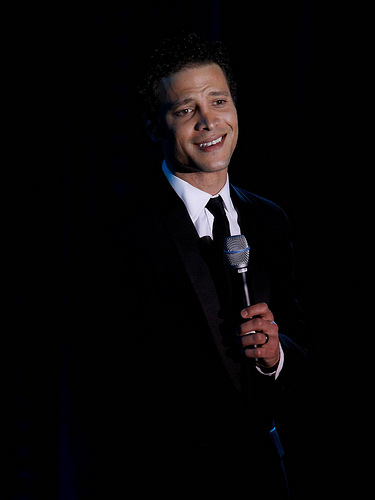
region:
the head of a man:
[131, 59, 275, 172]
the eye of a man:
[163, 93, 206, 133]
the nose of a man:
[191, 93, 227, 142]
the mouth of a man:
[187, 121, 251, 163]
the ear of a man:
[140, 110, 172, 159]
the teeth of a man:
[187, 121, 248, 169]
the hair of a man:
[147, 16, 257, 123]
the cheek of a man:
[166, 88, 218, 167]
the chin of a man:
[185, 160, 242, 206]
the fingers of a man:
[229, 299, 280, 398]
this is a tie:
[211, 198, 230, 231]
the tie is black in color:
[207, 199, 223, 231]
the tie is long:
[208, 197, 230, 225]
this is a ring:
[259, 334, 270, 346]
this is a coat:
[107, 227, 155, 319]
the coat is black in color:
[113, 305, 188, 428]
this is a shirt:
[192, 193, 207, 217]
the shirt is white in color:
[190, 191, 202, 203]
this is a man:
[143, 46, 320, 356]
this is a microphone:
[220, 237, 264, 307]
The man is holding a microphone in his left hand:
[224, 234, 276, 370]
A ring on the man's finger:
[261, 333, 269, 343]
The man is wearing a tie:
[207, 198, 229, 258]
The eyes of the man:
[177, 99, 226, 115]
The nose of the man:
[197, 105, 217, 130]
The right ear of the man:
[148, 118, 158, 139]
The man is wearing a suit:
[62, 163, 298, 499]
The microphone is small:
[224, 235, 257, 333]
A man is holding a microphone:
[57, 32, 311, 498]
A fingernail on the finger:
[241, 308, 248, 320]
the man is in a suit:
[58, 171, 333, 497]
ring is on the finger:
[257, 330, 271, 343]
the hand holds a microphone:
[220, 233, 281, 371]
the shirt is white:
[175, 178, 240, 232]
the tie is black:
[197, 194, 232, 226]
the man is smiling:
[113, 47, 348, 499]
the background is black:
[19, 15, 101, 108]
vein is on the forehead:
[163, 79, 182, 96]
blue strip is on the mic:
[216, 242, 257, 255]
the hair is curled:
[142, 37, 205, 63]